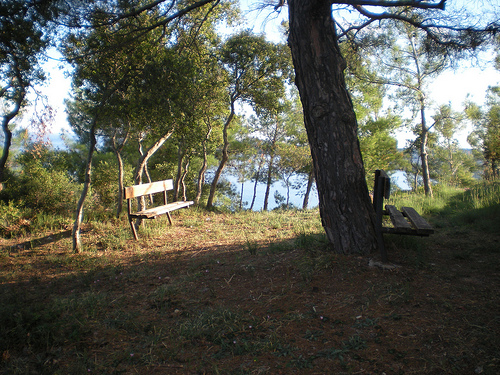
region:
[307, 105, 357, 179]
bark on tee trunk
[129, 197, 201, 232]
wood seat on bench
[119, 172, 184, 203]
back of wood bench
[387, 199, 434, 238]
two wood boards of seat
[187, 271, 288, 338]
green grass and dirt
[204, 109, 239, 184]
crooked trunk of tree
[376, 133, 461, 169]
horizon of water in distance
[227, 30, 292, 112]
green leaves on trees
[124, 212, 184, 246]
two legs on bench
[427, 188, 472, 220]
shadow of trees on grass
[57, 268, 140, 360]
this is the grass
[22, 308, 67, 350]
the grass is green in color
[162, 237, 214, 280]
this is some sand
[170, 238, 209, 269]
the sand is brown in color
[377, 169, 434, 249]
this is a bench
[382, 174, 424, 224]
the bench is wooden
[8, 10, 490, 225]
these are some trees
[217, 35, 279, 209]
the trees are short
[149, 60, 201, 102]
the leaves are green in color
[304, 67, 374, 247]
this is a tree trunk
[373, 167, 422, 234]
a bench right next to the tree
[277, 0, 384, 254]
a tall tree trunk by the bench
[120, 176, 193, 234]
another wooden bench for people to sit on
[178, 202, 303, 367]
a path for people to walk on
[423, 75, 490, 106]
a patch of blue sky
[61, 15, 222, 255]
some green leafy trees behind the bench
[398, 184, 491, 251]
some tall green grass next to a tree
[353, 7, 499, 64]
a long tree branch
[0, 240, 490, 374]
a section covered in shadows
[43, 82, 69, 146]
some more blue sky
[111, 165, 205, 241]
This is a bench.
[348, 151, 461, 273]
This bench seems to be fastened to the tree.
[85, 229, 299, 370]
The grass is sparse.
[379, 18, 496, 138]
The sky is bright with clouds.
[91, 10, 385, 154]
The trees appear small.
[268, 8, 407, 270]
This tree has a large trunk.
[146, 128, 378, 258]
The shadows make it appear to be evening.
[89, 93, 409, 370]
The ground is sloping.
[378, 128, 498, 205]
A building is in the background.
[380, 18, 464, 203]
This tree doesn't have many leaves.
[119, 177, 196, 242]
wooden bench in forest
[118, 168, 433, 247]
two wooden benches in forest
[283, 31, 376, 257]
wooden tree trunk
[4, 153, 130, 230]
green brush, shrubs and foliage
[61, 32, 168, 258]
tall green tree with thin tree trunk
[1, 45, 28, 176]
curved tree trunk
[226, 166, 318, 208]
body of water beyond tall thin green trees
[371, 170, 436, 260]
wooden bench in front of tree trunk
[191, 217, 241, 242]
patch of green grass and dirt ground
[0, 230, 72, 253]
shadow on ground of tall tree trunk